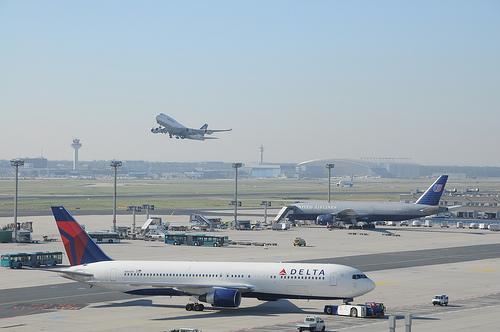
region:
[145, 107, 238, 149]
plane taking off into the sky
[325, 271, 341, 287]
door on an airplane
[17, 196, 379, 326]
airplane sitting on the runway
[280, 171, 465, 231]
airplane sitting on the runway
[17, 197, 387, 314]
airplane painted white and blue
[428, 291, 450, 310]
white van on the runway near airplane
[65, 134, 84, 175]
air traffic control tower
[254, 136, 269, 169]
air traffic control tower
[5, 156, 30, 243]
large outdoor lights on a metal pole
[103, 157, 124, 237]
large outdoor lights on a metal pole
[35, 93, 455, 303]
three airplanes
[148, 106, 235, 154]
airplane lifting off into the sky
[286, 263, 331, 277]
black lettering on white background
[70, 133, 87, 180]
air traffic control tower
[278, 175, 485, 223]
gray plane with blue tail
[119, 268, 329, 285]
row of windows on side of white airplane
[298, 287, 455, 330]
trucks driving through the airplane lot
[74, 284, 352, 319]
shadow of the white airpalne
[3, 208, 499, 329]
dark gray stripe on the pavement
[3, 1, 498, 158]
blue of daytime sky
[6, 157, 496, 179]
hazy horizon of airport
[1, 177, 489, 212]
green field of airport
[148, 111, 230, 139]
commercial plane taking off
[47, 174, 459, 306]
two planes on tarmac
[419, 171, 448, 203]
logo on blue tail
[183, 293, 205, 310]
wheels of landing gear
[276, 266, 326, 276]
airline logo on plane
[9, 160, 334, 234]
four lights on poles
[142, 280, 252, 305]
jet engine under wing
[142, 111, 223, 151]
plane taking off from airport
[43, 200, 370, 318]
white airplane parked at the airport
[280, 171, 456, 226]
gray airplane parked at the airport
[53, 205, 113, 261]
blue and red tail of the airplane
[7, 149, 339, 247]
four lights on the airport parking lot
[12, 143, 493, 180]
mountains in the distance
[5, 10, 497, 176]
blue sky fading to white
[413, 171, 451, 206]
blue tail of the gray airplane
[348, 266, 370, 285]
windows on the cockpit of white airplane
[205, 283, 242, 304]
engine of the white airplane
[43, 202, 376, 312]
plane sitting at airport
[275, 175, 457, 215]
plane sitting at airport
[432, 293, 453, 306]
vehicle used at airport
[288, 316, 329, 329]
vehicle used at airport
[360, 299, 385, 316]
vehicle used at airport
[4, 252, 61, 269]
vehicle used at airport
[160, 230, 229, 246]
vehicle used at airport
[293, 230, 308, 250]
vehicle used at airport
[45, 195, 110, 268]
blue and red tail of plane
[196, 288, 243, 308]
blue engine of plane